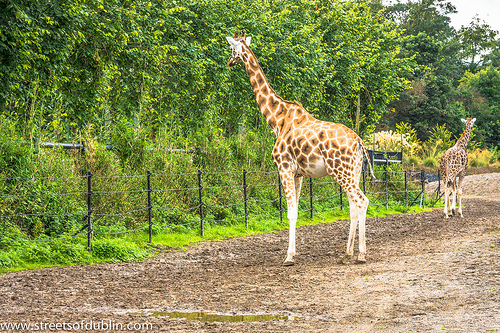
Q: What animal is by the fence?
A: A giraffe.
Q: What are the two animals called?
A: Giraffes.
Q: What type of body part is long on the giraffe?
A: The neck.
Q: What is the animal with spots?
A: A giraffe.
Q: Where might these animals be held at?
A: A zoo.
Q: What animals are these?
A: Giraffes.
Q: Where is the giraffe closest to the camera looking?
A: Into the woods.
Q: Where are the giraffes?
A: In a fenced area.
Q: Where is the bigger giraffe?
A: Closer to the camera.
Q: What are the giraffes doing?
A: Standing.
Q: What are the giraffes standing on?
A: Muddy ground.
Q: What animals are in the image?
A: Giraffes.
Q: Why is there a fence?
A: To contain the giraffes.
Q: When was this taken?
A: During the day.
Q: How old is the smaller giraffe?
A: It is a juvenile.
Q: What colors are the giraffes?
A: Brown and yellow.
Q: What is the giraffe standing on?
A: Dirt.